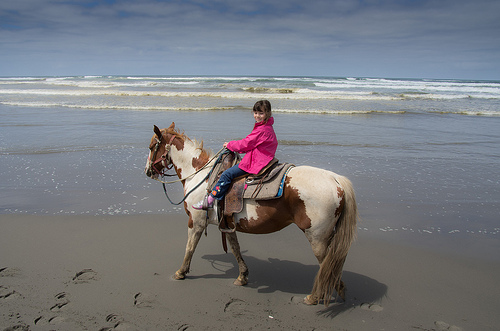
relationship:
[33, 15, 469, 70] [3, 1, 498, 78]
clouds floating in sky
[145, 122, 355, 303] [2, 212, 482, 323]
horse on beach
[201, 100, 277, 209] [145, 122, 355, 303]
girl on horse